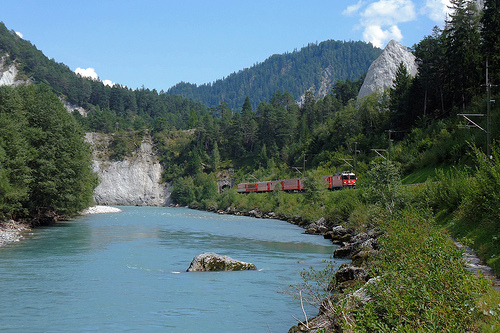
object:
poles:
[480, 83, 495, 158]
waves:
[123, 261, 184, 275]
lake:
[0, 201, 354, 332]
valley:
[0, 95, 500, 331]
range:
[0, 19, 226, 207]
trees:
[207, 139, 221, 173]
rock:
[185, 252, 258, 272]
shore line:
[170, 193, 382, 332]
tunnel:
[216, 177, 235, 193]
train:
[235, 169, 356, 195]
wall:
[78, 132, 176, 207]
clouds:
[358, 23, 404, 51]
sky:
[0, 0, 500, 97]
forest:
[171, 0, 500, 332]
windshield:
[341, 173, 358, 181]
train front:
[340, 172, 362, 187]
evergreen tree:
[19, 70, 100, 234]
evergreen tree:
[1, 83, 35, 221]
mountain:
[152, 37, 383, 115]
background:
[0, 0, 500, 332]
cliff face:
[85, 129, 177, 207]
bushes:
[453, 137, 500, 223]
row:
[329, 197, 489, 332]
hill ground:
[78, 203, 116, 216]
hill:
[355, 39, 421, 115]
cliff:
[81, 129, 175, 207]